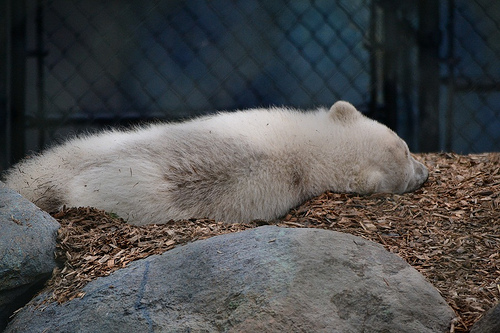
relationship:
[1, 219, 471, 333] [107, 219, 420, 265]
rock has an edge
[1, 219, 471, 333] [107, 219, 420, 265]
rock has a side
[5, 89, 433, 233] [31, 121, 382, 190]
dog seen back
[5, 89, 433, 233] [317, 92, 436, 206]
dog seen head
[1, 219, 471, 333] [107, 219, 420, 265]
rock seen side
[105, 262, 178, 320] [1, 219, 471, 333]
mark on stone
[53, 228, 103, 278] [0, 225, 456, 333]
gap between rock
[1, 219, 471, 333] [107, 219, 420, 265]
stone has edge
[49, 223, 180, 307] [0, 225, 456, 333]
chips spread over rock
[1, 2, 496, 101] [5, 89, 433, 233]
fence behind bear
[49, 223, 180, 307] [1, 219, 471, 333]
chips are on slope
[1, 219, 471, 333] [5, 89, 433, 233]
stone by bear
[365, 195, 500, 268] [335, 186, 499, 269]
chips are on ground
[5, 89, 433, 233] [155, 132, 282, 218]
fur has gray spot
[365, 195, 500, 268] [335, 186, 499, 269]
woodchips are on ground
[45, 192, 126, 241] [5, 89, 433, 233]
woodchips in fur of bear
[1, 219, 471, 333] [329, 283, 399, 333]
rock has spot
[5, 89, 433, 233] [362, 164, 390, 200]
bear has an ear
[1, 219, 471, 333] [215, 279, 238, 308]
rock has part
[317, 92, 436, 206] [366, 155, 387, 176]
head has part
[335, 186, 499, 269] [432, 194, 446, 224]
surface has part